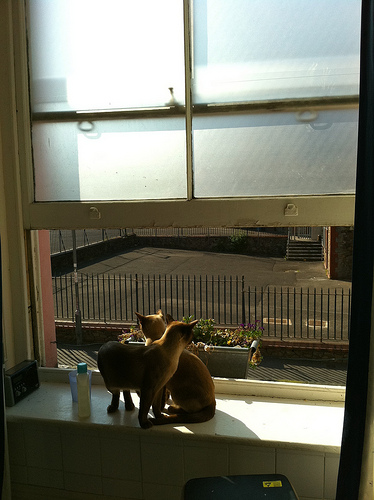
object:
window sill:
[38, 366, 106, 386]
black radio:
[5, 358, 41, 409]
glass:
[188, 0, 362, 108]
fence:
[49, 227, 286, 256]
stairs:
[286, 252, 324, 256]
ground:
[129, 328, 251, 349]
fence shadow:
[56, 342, 347, 388]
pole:
[71, 227, 85, 345]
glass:
[68, 367, 94, 402]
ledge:
[5, 381, 346, 453]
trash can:
[181, 472, 302, 500]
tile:
[274, 452, 324, 500]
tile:
[183, 444, 229, 484]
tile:
[99, 435, 143, 481]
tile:
[22, 420, 65, 473]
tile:
[139, 440, 186, 487]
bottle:
[75, 363, 91, 418]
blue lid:
[77, 362, 87, 373]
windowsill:
[210, 375, 345, 402]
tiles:
[323, 457, 342, 500]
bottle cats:
[76, 313, 201, 431]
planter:
[124, 324, 261, 380]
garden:
[118, 315, 266, 380]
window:
[8, 0, 362, 403]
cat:
[97, 314, 199, 429]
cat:
[133, 308, 216, 426]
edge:
[32, 366, 347, 402]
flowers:
[227, 339, 233, 346]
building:
[0, 0, 374, 500]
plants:
[180, 314, 266, 368]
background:
[47, 222, 353, 290]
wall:
[4, 419, 340, 500]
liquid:
[69, 379, 91, 401]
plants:
[117, 318, 146, 345]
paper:
[26, 0, 185, 115]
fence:
[52, 274, 352, 342]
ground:
[246, 342, 347, 386]